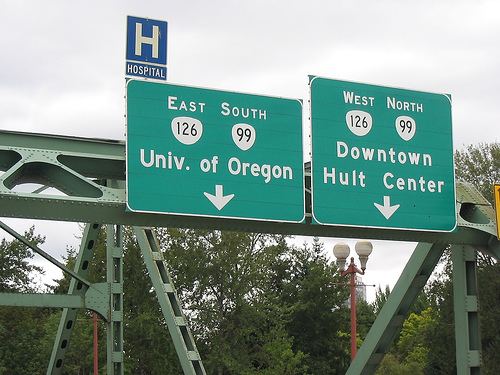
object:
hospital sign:
[123, 13, 171, 84]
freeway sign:
[121, 77, 306, 226]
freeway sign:
[306, 73, 458, 233]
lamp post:
[328, 238, 378, 364]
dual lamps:
[332, 241, 352, 272]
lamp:
[354, 240, 373, 272]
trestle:
[0, 129, 500, 374]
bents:
[483, 226, 493, 238]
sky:
[0, 0, 500, 335]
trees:
[202, 294, 316, 375]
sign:
[493, 182, 500, 243]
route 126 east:
[167, 95, 206, 146]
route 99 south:
[219, 101, 267, 152]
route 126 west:
[342, 90, 375, 137]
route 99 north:
[384, 94, 424, 142]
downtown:
[334, 140, 433, 168]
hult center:
[322, 164, 446, 193]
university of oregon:
[137, 147, 294, 184]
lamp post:
[76, 306, 106, 375]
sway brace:
[0, 220, 109, 300]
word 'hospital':
[127, 64, 166, 79]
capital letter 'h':
[133, 22, 159, 59]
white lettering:
[136, 94, 294, 211]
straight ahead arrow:
[203, 184, 236, 213]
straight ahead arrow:
[372, 194, 402, 221]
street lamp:
[327, 239, 377, 366]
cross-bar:
[328, 283, 375, 287]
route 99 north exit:
[371, 95, 424, 221]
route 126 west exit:
[322, 89, 401, 220]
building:
[335, 271, 368, 311]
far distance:
[190, 237, 448, 322]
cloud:
[255, 233, 445, 303]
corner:
[454, 178, 497, 261]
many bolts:
[2, 143, 500, 316]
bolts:
[115, 204, 119, 208]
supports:
[449, 244, 484, 375]